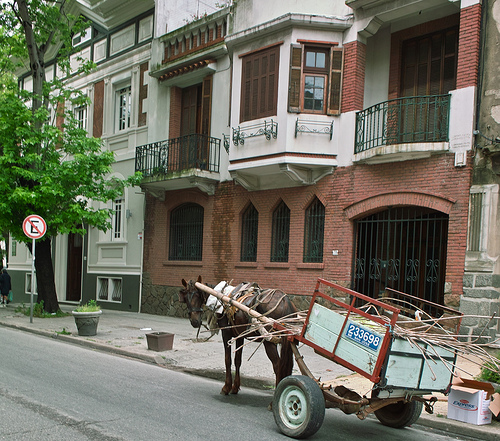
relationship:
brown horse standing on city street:
[179, 274, 291, 400] [6, 323, 290, 434]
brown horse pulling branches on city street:
[176, 273, 301, 402] [0, 291, 500, 440]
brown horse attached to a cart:
[176, 273, 301, 402] [272, 272, 467, 421]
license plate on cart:
[344, 321, 386, 351] [272, 272, 467, 421]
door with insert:
[56, 226, 88, 291] [61, 230, 91, 297]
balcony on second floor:
[123, 128, 232, 193] [127, 17, 277, 266]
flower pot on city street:
[72, 302, 108, 343] [10, 300, 151, 416]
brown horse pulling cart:
[176, 273, 301, 402] [272, 244, 473, 438]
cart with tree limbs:
[296, 268, 492, 426] [376, 302, 494, 394]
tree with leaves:
[5, 59, 101, 340] [18, 150, 78, 211]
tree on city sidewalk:
[5, 59, 101, 340] [3, 295, 128, 438]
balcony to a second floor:
[339, 97, 462, 169] [341, 4, 488, 191]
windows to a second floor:
[248, 44, 318, 116] [130, 10, 352, 203]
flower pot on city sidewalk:
[71, 305, 103, 337] [1, 319, 500, 441]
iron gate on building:
[347, 195, 456, 335] [316, 17, 496, 313]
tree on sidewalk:
[0, 0, 130, 318] [21, 322, 211, 432]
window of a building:
[90, 59, 153, 148] [41, 17, 188, 375]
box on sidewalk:
[447, 375, 500, 428] [423, 402, 486, 434]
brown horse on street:
[176, 273, 301, 402] [158, 386, 267, 431]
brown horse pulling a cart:
[176, 273, 301, 402] [301, 279, 477, 413]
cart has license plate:
[268, 272, 466, 441] [344, 322, 383, 353]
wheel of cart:
[266, 375, 329, 437] [285, 272, 443, 416]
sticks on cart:
[393, 286, 462, 358] [272, 272, 467, 421]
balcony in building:
[123, 128, 232, 193] [124, 8, 273, 328]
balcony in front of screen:
[123, 128, 232, 193] [182, 91, 193, 140]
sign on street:
[15, 207, 48, 335] [7, 315, 92, 440]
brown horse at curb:
[176, 273, 301, 402] [101, 346, 211, 376]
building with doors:
[140, 102, 459, 296] [355, 200, 444, 296]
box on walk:
[445, 377, 493, 437] [431, 402, 491, 440]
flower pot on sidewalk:
[71, 305, 103, 337] [25, 306, 77, 329]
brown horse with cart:
[176, 273, 301, 402] [292, 270, 453, 413]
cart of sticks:
[268, 272, 466, 441] [385, 294, 471, 347]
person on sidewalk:
[3, 260, 17, 305] [6, 298, 34, 329]